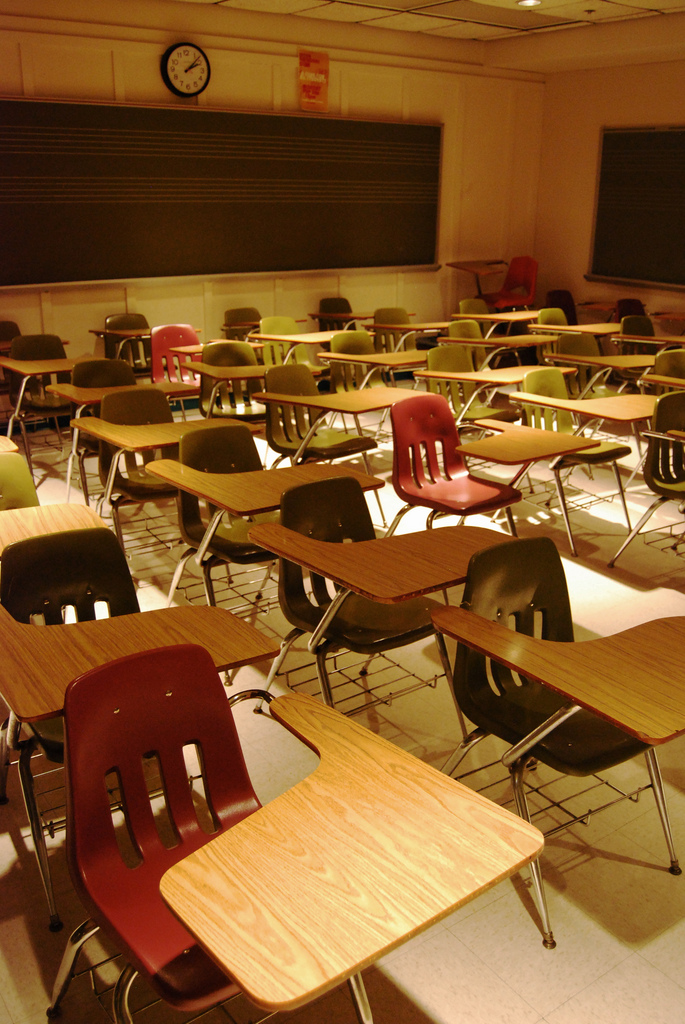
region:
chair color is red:
[58, 643, 284, 1016]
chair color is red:
[387, 395, 527, 539]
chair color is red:
[148, 317, 223, 393]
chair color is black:
[460, 539, 682, 942]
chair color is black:
[274, 471, 461, 754]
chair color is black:
[8, 527, 187, 762]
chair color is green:
[517, 363, 633, 550]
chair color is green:
[202, 337, 265, 427]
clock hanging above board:
[154, 37, 211, 100]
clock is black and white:
[156, 35, 216, 103]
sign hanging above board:
[288, 40, 336, 118]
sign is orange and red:
[286, 38, 338, 113]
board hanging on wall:
[2, 85, 450, 293]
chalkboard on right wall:
[577, 117, 683, 287]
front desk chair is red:
[32, 634, 294, 1021]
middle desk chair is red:
[382, 393, 535, 565]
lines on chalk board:
[0, 115, 443, 230]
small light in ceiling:
[517, 0, 548, 14]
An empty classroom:
[1, 98, 684, 1017]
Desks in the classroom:
[1, 252, 683, 1022]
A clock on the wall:
[159, 39, 212, 99]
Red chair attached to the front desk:
[38, 646, 263, 1021]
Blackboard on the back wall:
[0, 98, 445, 290]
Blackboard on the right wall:
[581, 120, 683, 294]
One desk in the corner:
[445, 253, 542, 314]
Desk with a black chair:
[423, 532, 681, 944]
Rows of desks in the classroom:
[4, 292, 684, 1018]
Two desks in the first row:
[2, 521, 544, 1020]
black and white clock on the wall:
[158, 39, 211, 97]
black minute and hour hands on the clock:
[179, 55, 205, 73]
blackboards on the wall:
[10, 91, 684, 283]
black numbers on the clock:
[164, 42, 209, 95]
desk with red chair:
[383, 393, 572, 523]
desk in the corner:
[448, 238, 535, 309]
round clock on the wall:
[159, 41, 212, 98]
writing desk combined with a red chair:
[45, 641, 541, 1020]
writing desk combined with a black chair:
[426, 532, 682, 947]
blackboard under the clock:
[0, 94, 445, 290]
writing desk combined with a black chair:
[247, 473, 518, 714]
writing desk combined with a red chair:
[381, 392, 602, 558]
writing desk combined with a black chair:
[144, 422, 385, 608]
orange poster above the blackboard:
[295, 46, 333, 113]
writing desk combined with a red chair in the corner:
[444, 252, 536, 336]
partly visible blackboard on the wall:
[581, 121, 683, 292]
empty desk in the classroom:
[264, 479, 519, 744]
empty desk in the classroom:
[147, 411, 381, 604]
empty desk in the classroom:
[65, 380, 258, 546]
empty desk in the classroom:
[259, 344, 431, 479]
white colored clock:
[154, 40, 208, 107]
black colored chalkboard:
[3, 93, 436, 289]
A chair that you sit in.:
[372, 381, 525, 560]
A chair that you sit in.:
[250, 364, 401, 531]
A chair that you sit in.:
[257, 470, 480, 744]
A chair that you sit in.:
[402, 527, 681, 913]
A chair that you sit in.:
[115, 420, 340, 694]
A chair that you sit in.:
[192, 334, 306, 465]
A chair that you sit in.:
[126, 306, 235, 422]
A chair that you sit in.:
[92, 301, 179, 393]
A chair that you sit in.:
[7, 332, 107, 499]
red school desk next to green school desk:
[382, 393, 601, 544]